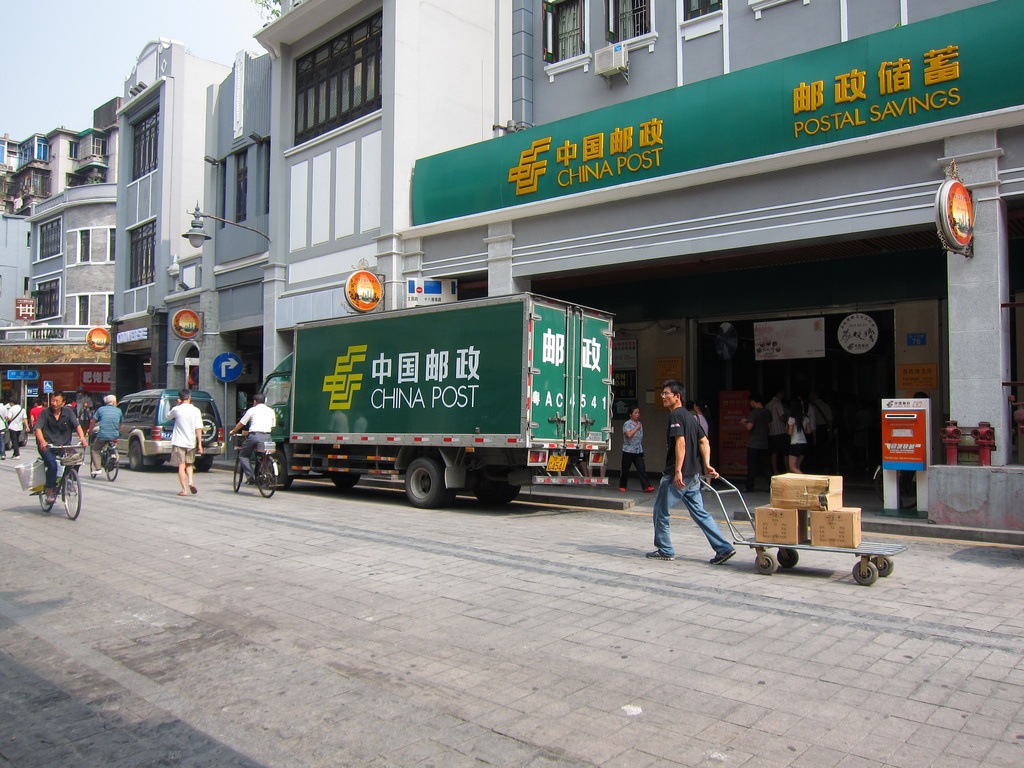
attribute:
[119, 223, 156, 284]
glass — clean, clear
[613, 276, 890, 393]
glass — clean and clear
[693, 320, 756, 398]
glass — clean and clear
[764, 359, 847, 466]
glass — clean and clear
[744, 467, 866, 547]
boxes — 3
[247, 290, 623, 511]
truck — large, green, delivery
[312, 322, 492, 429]
graphics — white and yellow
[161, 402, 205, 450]
t-shirt — white 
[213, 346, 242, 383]
turn sign — blue and white, right-hand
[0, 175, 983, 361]
signs — 4, round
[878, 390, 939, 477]
box — red, white, and blue, drop-off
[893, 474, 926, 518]
post — black